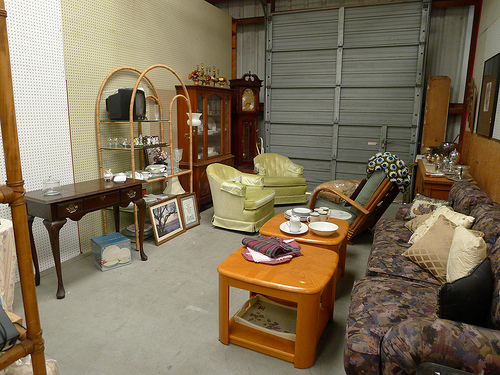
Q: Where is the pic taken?
A: Garage.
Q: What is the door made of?
A: Metal.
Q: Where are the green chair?
A: In front of the wooden cabinet.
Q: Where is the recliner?
A: By the tables.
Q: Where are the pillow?
A: On the couch.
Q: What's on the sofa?
A: Pillows.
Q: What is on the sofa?
A: Pillows.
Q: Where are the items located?
A: Storage facility.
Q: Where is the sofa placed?
A: Against the wall.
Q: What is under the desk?
A: A box.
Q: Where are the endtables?
A: In front of the sofa.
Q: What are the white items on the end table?
A: Set of dishes.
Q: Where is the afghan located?
A: On a green rocking chair.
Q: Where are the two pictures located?
A: On the floor.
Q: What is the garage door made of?
A: Metal.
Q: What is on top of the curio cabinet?
A: A set of candleholders.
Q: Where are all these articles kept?
A: Storage.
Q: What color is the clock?
A: Brown.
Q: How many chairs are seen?
A: Three.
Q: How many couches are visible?
A: One.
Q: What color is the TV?
A: Black.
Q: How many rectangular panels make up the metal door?
A: Ten.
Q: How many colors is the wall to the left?
A: Two.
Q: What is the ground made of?
A: Concrete.